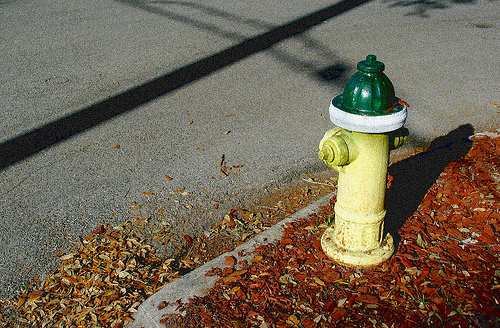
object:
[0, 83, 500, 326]
sidewalk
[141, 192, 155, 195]
leaves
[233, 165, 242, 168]
leaves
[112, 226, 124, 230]
leaves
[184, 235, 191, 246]
leaves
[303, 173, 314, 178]
leaves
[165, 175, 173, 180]
leaves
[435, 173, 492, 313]
flower bed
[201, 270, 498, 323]
dirt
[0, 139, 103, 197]
crack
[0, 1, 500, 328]
pavement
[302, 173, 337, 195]
small stick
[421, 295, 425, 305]
grass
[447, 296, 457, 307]
grass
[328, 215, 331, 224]
grass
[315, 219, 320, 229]
grass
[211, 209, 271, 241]
leaves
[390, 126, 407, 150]
bolt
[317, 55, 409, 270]
fire hydrant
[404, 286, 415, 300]
grass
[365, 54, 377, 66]
bolt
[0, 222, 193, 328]
leaves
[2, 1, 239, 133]
ground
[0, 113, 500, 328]
mulch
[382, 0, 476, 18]
shadow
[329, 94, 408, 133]
trim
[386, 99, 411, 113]
leaves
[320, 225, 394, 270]
bottom